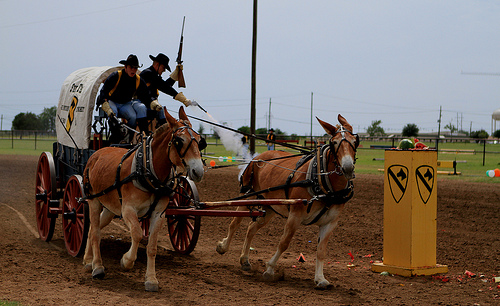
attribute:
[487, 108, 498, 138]
water tower — in the back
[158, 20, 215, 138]
shotgun — in the air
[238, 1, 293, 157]
pole — the pole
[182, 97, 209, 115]
shooter — silver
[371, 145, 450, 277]
pole — yellow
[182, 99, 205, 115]
pistol — being shot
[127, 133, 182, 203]
harness — black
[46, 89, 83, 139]
logo wagon — on the side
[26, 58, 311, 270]
wagon — old